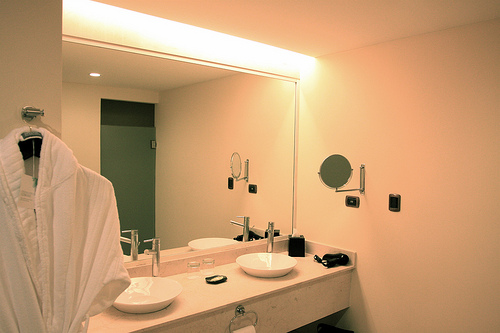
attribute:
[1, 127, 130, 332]
robe — terry cloth, new, hanging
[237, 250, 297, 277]
double sinks — round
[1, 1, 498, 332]
bathroom — lighted, illuminated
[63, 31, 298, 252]
silver beveled — large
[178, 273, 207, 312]
vanity counter — white, beige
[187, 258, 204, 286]
cups — glass, water glasses, wtaer glasses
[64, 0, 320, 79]
light fixture — long, dome lighting, fluorescent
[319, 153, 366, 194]
mirror — personal magnifier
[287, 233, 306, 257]
tissue box — black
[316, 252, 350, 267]
hair dryer — black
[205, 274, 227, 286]
soap dish — black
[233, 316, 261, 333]
toilet paper — roll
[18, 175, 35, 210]
tag — white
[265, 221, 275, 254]
faucets — metal